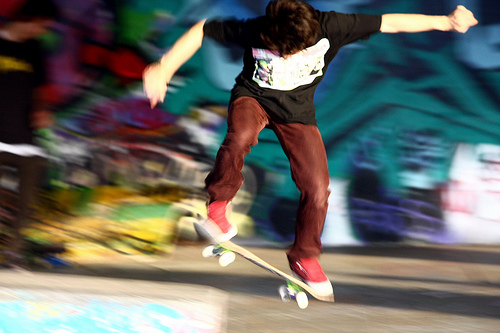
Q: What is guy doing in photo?
A: On a skateboard.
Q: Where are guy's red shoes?
A: On skateboard.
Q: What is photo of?
A: Guy on skateboard.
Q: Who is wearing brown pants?
A: The man.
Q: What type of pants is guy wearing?
A: Brown pants.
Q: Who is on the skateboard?
A: Man in brown pants.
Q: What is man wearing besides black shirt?
A: Brown pants.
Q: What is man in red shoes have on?
A: Brown pants.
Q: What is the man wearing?
A: Brown pants.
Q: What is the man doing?
A: Skating.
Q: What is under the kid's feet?
A: Skateboard.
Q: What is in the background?
A: Paint.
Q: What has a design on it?
A: The shirt.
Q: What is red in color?
A: The shoes.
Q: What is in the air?
A: A skateboard.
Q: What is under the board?
A: Wheels.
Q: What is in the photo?
A: A skateboard.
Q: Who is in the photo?
A: A skater.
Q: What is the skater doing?
A: Skating.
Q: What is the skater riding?
A: A skateboard.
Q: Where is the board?
A: In the air.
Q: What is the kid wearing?
A: Pants.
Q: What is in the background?
A: Graffiti.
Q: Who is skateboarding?
A: The man.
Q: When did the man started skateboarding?
A: Earlier.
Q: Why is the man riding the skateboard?
A: For skateboarding.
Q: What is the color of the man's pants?
A: Brown.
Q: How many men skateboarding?
A: One.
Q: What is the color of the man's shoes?
A: Red.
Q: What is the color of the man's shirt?
A: Black.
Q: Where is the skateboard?
A: At the park.